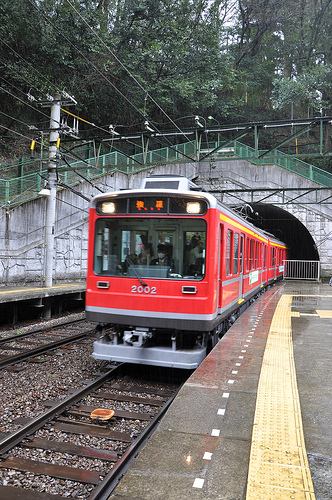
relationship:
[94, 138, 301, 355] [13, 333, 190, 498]
subway on track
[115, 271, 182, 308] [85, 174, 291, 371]
number on subway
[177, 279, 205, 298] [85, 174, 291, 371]
headlight on subway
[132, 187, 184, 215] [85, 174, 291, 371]
sign on subway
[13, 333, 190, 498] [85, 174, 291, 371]
track for subway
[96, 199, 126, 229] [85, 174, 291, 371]
light on subway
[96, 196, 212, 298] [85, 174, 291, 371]
windhield on subway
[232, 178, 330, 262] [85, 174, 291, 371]
tunnel for subway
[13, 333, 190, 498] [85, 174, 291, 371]
track with subway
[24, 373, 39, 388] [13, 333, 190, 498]
rock on track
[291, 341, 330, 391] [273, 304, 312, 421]
water on road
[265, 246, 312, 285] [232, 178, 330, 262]
fence by tunnel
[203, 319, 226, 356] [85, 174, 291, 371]
wheel on subway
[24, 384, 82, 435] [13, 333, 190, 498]
rail on track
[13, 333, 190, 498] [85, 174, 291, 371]
track has subway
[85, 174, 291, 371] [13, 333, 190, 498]
subway has track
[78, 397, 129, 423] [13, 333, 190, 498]
square on track